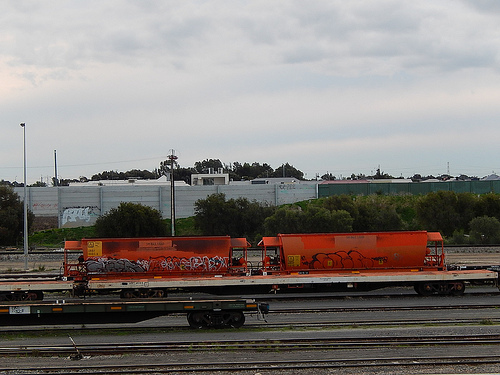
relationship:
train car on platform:
[257, 230, 448, 275] [2, 245, 499, 373]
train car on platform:
[60, 235, 253, 281] [2, 245, 499, 373]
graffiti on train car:
[86, 256, 229, 274] [60, 235, 253, 281]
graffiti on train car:
[300, 251, 388, 268] [257, 230, 448, 275]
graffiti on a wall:
[61, 205, 92, 223] [14, 179, 500, 233]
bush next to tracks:
[95, 199, 169, 237] [0, 242, 498, 255]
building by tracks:
[69, 168, 415, 186] [0, 242, 498, 255]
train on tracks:
[52, 230, 446, 288] [0, 271, 499, 373]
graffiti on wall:
[86, 256, 229, 274] [14, 179, 500, 233]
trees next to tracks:
[193, 191, 499, 245] [0, 242, 498, 255]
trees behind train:
[193, 191, 499, 245] [52, 230, 446, 288]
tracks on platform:
[0, 242, 498, 255] [2, 245, 499, 373]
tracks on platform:
[0, 271, 499, 373] [2, 245, 499, 373]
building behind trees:
[69, 168, 415, 186] [193, 191, 499, 245]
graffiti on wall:
[61, 205, 92, 223] [14, 179, 500, 233]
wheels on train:
[415, 276, 467, 294] [52, 230, 446, 288]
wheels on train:
[118, 288, 169, 299] [52, 230, 446, 288]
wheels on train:
[0, 289, 42, 299] [52, 230, 446, 288]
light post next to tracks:
[19, 121, 29, 270] [0, 242, 498, 255]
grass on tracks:
[2, 317, 499, 338] [0, 271, 499, 373]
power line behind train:
[166, 147, 179, 235] [52, 230, 446, 288]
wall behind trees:
[14, 179, 500, 233] [193, 191, 499, 245]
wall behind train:
[14, 179, 500, 233] [52, 230, 446, 288]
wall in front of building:
[14, 179, 500, 233] [69, 168, 415, 186]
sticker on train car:
[86, 239, 103, 258] [60, 235, 253, 281]